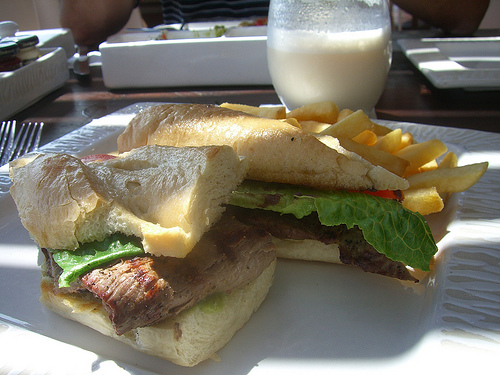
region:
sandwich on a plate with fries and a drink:
[5, 9, 495, 371]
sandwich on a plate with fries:
[116, 77, 458, 247]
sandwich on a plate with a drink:
[235, 5, 455, 290]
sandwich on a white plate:
[31, 137, 288, 370]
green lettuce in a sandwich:
[40, 157, 270, 338]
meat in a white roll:
[52, 223, 269, 350]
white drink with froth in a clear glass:
[246, 3, 404, 100]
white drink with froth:
[255, 2, 400, 103]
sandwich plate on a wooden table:
[48, 82, 208, 372]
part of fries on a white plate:
[388, 103, 495, 194]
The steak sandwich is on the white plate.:
[9, 141, 366, 373]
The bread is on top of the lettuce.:
[8, 151, 256, 284]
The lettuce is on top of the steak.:
[44, 236, 217, 327]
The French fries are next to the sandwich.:
[217, 95, 489, 227]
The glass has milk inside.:
[267, 2, 397, 112]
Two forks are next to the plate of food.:
[1, 106, 72, 184]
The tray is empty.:
[397, 28, 498, 85]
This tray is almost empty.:
[96, 2, 291, 79]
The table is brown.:
[27, 96, 125, 144]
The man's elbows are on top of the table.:
[38, 2, 143, 82]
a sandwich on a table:
[29, 62, 479, 374]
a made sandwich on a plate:
[7, 84, 411, 372]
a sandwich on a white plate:
[102, 104, 357, 366]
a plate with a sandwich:
[29, 78, 361, 373]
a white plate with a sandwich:
[54, 68, 402, 372]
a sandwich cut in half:
[54, 76, 399, 340]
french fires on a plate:
[165, 32, 499, 262]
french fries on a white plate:
[203, 56, 463, 233]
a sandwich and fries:
[58, 41, 403, 319]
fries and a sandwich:
[7, 57, 497, 351]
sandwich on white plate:
[12, 88, 453, 364]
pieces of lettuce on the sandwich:
[40, 187, 428, 286]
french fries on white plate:
[225, 90, 476, 206]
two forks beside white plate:
[2, 115, 41, 166]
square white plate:
[5, 99, 497, 371]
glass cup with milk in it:
[264, 5, 394, 112]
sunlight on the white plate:
[5, 98, 499, 374]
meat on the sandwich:
[82, 200, 372, 335]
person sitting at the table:
[60, 3, 490, 48]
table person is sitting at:
[1, 21, 497, 286]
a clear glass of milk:
[268, 0, 390, 111]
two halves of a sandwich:
[8, 103, 433, 368]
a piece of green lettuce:
[233, 185, 438, 274]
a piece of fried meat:
[33, 215, 275, 335]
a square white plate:
[1, 100, 498, 373]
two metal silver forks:
[0, 119, 46, 169]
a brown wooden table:
[0, 50, 499, 167]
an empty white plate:
[396, 35, 498, 86]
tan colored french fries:
[217, 102, 487, 215]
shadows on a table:
[0, 63, 487, 151]